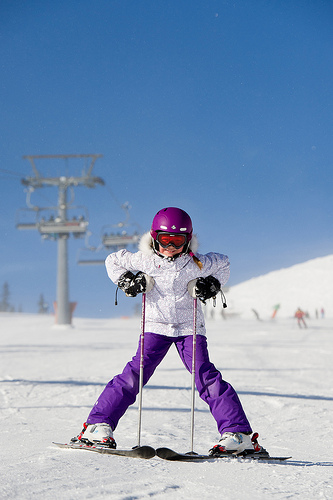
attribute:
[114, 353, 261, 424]
snowpants — here, purple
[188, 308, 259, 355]
poles — metal, large, skis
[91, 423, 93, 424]
shoes — here, white, edge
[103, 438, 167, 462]
skis — here, black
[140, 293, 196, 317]
jacket — purple, white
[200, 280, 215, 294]
gloves — black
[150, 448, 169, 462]
board — part, here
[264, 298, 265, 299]
hooker — here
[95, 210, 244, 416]
girl — skiing, posing, smiling, stopping, apart, standing, leg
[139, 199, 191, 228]
helmet — purple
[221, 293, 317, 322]
people — skiing, background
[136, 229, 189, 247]
goggles — red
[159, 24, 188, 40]
sky — blue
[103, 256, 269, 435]
outfit — purple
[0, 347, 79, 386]
snow — background